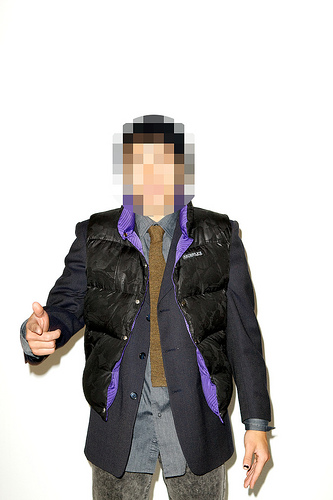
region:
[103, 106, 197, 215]
The person's face being censored.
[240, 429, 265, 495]
The person having black nail polish.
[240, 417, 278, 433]
The shirt has long sleeves.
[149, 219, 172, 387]
Brown and long tie.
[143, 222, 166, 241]
Single knotted tie.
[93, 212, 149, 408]
Black and purple vest.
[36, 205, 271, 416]
The man wearing a shirt, a jacket and a vest.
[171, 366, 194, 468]
Dark grey jacket.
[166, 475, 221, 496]
The man wearing black jean.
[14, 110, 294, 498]
The guy standing and pointing at something.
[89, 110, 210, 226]
pixellated blurred face of person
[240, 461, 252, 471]
black nail polish on thumb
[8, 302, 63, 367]
one hand pointing forward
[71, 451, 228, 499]
pair of black stone wash jeans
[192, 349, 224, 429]
purple lining of black vest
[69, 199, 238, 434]
black quilted vest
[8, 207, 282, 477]
grey suit jacket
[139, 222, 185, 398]
brown tie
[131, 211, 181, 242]
grey shirt collar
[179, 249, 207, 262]
white letters on front of black vase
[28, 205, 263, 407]
the man is wearing a jacket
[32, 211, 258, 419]
the jacket is black in color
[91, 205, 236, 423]
the man is wearing a vest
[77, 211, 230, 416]
the vest is black in color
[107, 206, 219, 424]
the vest has an inner lining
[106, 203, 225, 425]
the lining is blue in color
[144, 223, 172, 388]
the man is wearing a tie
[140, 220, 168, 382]
the tie is brown in color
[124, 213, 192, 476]
the man is wearing a shirt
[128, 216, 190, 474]
the shirt is grey in color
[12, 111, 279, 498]
Man in the photo.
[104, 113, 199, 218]
Digital pixels on the face.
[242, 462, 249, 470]
black nail polish on nail.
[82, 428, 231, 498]
Black jeans on the legs.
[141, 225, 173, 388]
Brown tie on the man.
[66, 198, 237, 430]
Black vest on the man.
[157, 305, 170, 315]
Button hole on the jacket.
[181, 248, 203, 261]
label on the jacket.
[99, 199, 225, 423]
Purple color inside the vest.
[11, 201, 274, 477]
Suit jacket on the man.